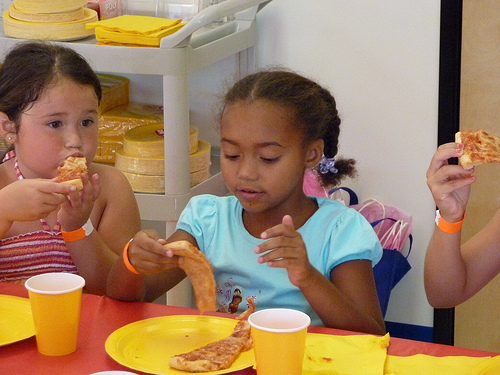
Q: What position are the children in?
A: Sitting.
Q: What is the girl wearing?
A: A t-shirt.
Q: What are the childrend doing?
A: Eating pizza.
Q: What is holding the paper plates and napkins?
A: Tray.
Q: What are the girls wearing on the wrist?
A: Wrist bands.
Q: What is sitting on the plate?
A: Pizza.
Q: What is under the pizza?
A: Yellow plate.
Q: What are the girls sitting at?
A: A table.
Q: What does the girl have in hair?
A: A purple ribbon.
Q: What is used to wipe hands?
A: Napkins.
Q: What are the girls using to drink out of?
A: Plastic cups.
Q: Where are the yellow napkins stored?
A: On the cart.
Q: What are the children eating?
A: Pizza.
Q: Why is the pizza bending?
A: Gravity.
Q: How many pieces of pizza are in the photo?
A: 4.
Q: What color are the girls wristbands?
A: Orange.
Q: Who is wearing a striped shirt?
A: The girl on the left.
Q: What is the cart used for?
A: Storing plates and napkins.